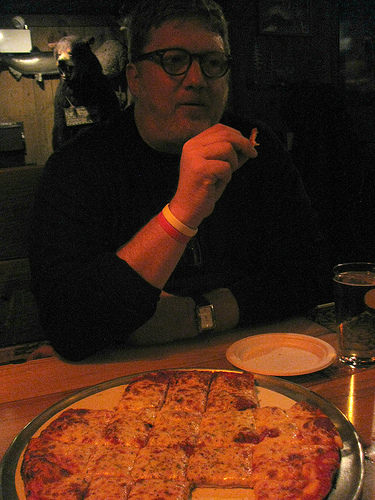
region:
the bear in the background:
[48, 34, 120, 151]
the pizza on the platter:
[20, 368, 343, 498]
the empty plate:
[226, 331, 335, 374]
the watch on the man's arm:
[190, 292, 216, 337]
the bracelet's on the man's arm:
[156, 202, 197, 244]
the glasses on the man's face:
[129, 46, 231, 79]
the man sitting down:
[28, 0, 329, 362]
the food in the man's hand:
[249, 126, 259, 150]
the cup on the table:
[332, 261, 373, 369]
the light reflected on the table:
[347, 367, 353, 427]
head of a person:
[120, 5, 251, 158]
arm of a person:
[120, 200, 201, 281]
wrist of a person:
[135, 205, 217, 237]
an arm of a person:
[115, 221, 207, 292]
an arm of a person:
[191, 268, 301, 337]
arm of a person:
[174, 272, 297, 348]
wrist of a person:
[195, 286, 228, 346]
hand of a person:
[126, 272, 207, 346]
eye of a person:
[162, 48, 194, 76]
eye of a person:
[201, 48, 245, 76]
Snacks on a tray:
[4, 366, 363, 497]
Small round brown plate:
[223, 327, 337, 377]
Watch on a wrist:
[185, 289, 217, 339]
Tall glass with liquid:
[326, 259, 373, 370]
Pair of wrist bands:
[150, 199, 205, 250]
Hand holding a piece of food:
[175, 121, 273, 212]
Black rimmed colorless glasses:
[125, 43, 235, 82]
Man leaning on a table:
[0, 0, 340, 374]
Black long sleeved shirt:
[20, 101, 338, 366]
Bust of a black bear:
[40, 30, 126, 163]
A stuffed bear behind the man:
[47, 34, 118, 154]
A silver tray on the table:
[0, 369, 365, 497]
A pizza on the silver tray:
[20, 372, 333, 497]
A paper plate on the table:
[227, 333, 336, 376]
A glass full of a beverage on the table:
[333, 261, 374, 362]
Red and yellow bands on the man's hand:
[160, 206, 196, 244]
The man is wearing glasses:
[129, 48, 233, 75]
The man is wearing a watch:
[192, 295, 215, 335]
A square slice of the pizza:
[134, 444, 188, 480]